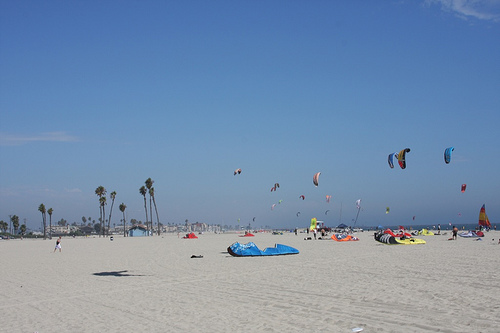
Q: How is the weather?
A: Slightly cloudy.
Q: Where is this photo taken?
A: The beach.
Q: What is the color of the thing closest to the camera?
A: Blue.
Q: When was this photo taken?
A: Day time.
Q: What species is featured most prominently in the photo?
A: Homo sapiens.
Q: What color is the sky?
A: Blue.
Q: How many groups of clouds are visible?
A: Three.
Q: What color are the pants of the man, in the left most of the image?
A: White.